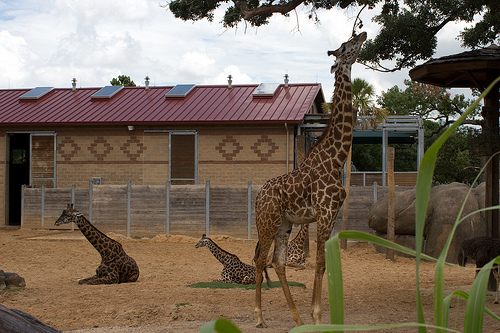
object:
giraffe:
[193, 230, 264, 283]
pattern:
[247, 135, 279, 162]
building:
[0, 73, 425, 233]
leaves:
[409, 79, 499, 332]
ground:
[0, 223, 499, 332]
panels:
[18, 85, 57, 101]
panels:
[88, 85, 126, 103]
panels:
[164, 84, 198, 100]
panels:
[249, 81, 280, 100]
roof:
[0, 73, 331, 124]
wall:
[0, 126, 295, 229]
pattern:
[54, 135, 82, 162]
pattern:
[216, 133, 246, 162]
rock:
[366, 180, 486, 266]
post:
[384, 143, 397, 262]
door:
[5, 133, 31, 227]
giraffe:
[54, 202, 141, 286]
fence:
[19, 180, 414, 239]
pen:
[0, 0, 499, 332]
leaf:
[356, 23, 365, 28]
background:
[0, 0, 499, 332]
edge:
[0, 116, 301, 129]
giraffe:
[249, 29, 371, 332]